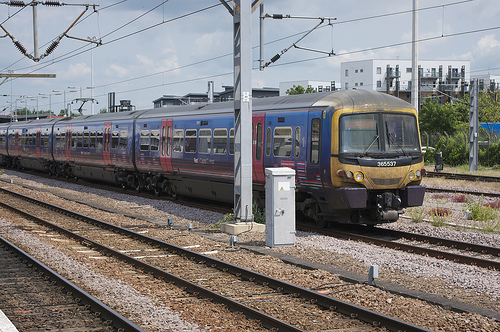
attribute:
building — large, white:
[338, 54, 471, 89]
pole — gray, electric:
[459, 73, 482, 170]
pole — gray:
[198, 17, 273, 239]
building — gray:
[338, 59, 470, 99]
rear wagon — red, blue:
[4, 121, 53, 158]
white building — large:
[277, 79, 339, 92]